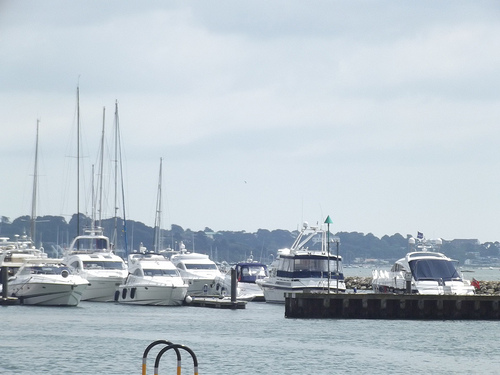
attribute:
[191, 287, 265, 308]
dock — wooden, grey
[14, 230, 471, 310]
boats — big, large, white, modern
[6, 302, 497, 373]
lake — clear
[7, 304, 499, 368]
water — clear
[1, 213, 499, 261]
trees — green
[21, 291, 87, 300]
stripe — blue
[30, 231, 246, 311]
boats — group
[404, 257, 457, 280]
front window — large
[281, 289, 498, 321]
dock — large and gray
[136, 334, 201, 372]
hand rail — yellow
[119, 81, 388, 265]
sky — hazy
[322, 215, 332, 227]
triangular object — green and triangular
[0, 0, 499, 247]
cloudy sky — blue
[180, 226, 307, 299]
dock — small and wooden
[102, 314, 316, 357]
water — blue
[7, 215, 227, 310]
boats — white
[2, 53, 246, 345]
boats — white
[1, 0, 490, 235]
sky — clear, blue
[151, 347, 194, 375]
portion — in gray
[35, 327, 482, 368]
line — white